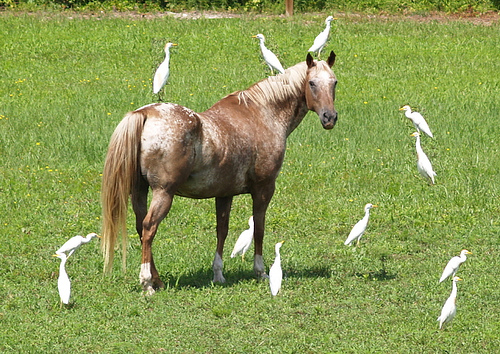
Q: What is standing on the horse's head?
A: Bird.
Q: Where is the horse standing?
A: Field.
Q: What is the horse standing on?
A: Grass.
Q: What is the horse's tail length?
A: Long.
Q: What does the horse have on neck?
A: Bird.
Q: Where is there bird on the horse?
A: Rear end.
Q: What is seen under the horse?
A: Shadow.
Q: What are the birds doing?
A: Standing.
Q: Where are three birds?
A: On top of the horse.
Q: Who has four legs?
A: The horse.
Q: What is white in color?
A: The birds.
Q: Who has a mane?
A: A horse.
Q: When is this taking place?
A: Daytime.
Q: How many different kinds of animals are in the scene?
A: Two.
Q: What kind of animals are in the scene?
A: Horse and bird.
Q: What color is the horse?
A: Brown and white.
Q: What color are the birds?
A: White.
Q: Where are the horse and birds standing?
A: Field.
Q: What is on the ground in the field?
A: Grass.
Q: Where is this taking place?
A: In a field.